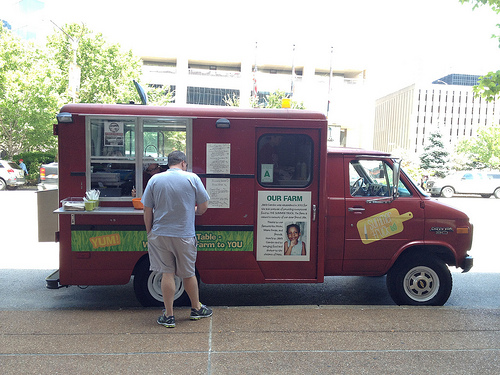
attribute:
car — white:
[421, 168, 498, 200]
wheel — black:
[386, 249, 453, 307]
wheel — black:
[131, 253, 196, 310]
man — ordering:
[141, 153, 213, 328]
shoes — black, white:
[153, 297, 217, 334]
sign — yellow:
[354, 204, 416, 247]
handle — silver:
[200, 168, 261, 188]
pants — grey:
[140, 227, 200, 280]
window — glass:
[417, 87, 422, 102]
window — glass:
[431, 87, 436, 104]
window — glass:
[441, 104, 450, 116]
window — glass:
[483, 107, 488, 117]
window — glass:
[413, 125, 420, 135]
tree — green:
[2, 18, 55, 160]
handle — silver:
[344, 201, 370, 214]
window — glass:
[448, 115, 456, 125]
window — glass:
[415, 85, 422, 100]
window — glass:
[468, 104, 478, 119]